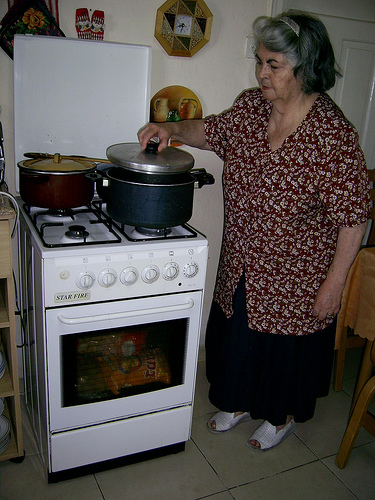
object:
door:
[268, 1, 374, 246]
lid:
[106, 136, 194, 175]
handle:
[57, 298, 202, 328]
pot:
[19, 152, 94, 206]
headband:
[270, 14, 308, 42]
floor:
[1, 345, 374, 499]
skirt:
[194, 262, 345, 343]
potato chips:
[99, 346, 168, 396]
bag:
[96, 346, 169, 389]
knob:
[75, 272, 96, 291]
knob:
[99, 273, 119, 289]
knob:
[119, 264, 139, 283]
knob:
[141, 262, 160, 286]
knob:
[162, 262, 178, 280]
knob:
[182, 262, 199, 276]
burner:
[35, 212, 119, 246]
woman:
[139, 11, 367, 447]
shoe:
[247, 412, 299, 454]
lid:
[16, 150, 96, 175]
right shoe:
[209, 402, 247, 434]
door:
[42, 284, 210, 438]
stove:
[11, 183, 210, 470]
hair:
[251, 11, 345, 101]